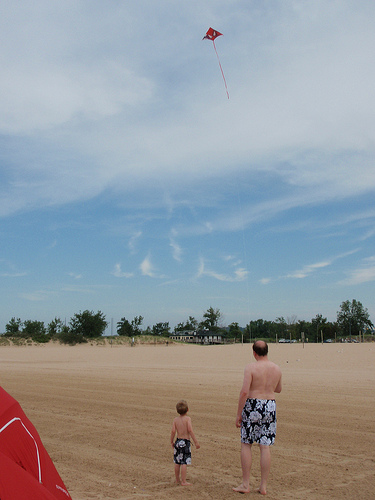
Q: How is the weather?
A: It is clear.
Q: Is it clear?
A: Yes, it is clear.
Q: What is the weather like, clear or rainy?
A: It is clear.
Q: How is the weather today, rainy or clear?
A: It is clear.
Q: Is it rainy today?
A: No, it is clear.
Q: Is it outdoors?
A: Yes, it is outdoors.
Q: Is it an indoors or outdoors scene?
A: It is outdoors.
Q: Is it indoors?
A: No, it is outdoors.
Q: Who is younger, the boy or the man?
A: The boy is younger than the man.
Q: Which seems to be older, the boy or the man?
A: The man is older than the boy.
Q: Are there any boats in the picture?
A: No, there are no boats.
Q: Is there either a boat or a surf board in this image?
A: No, there are no boats or surfboards.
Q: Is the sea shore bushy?
A: Yes, the sea shore is bushy.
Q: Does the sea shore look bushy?
A: Yes, the sea shore is bushy.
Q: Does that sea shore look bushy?
A: Yes, the sea shore is bushy.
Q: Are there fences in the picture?
A: No, there are no fences.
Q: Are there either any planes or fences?
A: No, there are no fences or planes.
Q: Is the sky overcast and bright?
A: No, the sky is bright but clear.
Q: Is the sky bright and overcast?
A: No, the sky is bright but clear.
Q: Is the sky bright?
A: Yes, the sky is bright.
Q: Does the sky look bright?
A: Yes, the sky is bright.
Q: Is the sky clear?
A: Yes, the sky is clear.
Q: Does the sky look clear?
A: Yes, the sky is clear.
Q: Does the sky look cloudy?
A: No, the sky is clear.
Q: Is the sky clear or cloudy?
A: The sky is clear.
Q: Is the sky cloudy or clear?
A: The sky is clear.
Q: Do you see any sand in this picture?
A: Yes, there is sand.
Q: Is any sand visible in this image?
A: Yes, there is sand.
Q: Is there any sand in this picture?
A: Yes, there is sand.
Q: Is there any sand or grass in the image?
A: Yes, there is sand.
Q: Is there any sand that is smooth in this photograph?
A: Yes, there is smooth sand.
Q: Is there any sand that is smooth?
A: Yes, there is sand that is smooth.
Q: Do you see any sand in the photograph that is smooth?
A: Yes, there is sand that is smooth.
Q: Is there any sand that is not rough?
A: Yes, there is smooth sand.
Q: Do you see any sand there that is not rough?
A: Yes, there is smooth sand.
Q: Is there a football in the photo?
A: No, there are no footballs.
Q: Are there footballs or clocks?
A: No, there are no footballs or clocks.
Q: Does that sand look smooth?
A: Yes, the sand is smooth.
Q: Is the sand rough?
A: No, the sand is smooth.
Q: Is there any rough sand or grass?
A: No, there is sand but it is smooth.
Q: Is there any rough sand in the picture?
A: No, there is sand but it is smooth.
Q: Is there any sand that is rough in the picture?
A: No, there is sand but it is smooth.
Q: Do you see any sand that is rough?
A: No, there is sand but it is smooth.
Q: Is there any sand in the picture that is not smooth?
A: No, there is sand but it is smooth.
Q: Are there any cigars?
A: No, there are no cigars.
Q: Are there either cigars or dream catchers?
A: No, there are no cigars or dream catchers.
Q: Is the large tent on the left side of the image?
A: Yes, the tent is on the left of the image.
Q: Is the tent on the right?
A: No, the tent is on the left of the image.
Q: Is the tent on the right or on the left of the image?
A: The tent is on the left of the image.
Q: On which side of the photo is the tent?
A: The tent is on the left of the image.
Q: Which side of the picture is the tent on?
A: The tent is on the left of the image.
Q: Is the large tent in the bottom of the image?
A: Yes, the tent is in the bottom of the image.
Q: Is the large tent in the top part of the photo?
A: No, the tent is in the bottom of the image.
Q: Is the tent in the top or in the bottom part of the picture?
A: The tent is in the bottom of the image.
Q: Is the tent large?
A: Yes, the tent is large.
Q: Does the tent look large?
A: Yes, the tent is large.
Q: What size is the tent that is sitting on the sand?
A: The tent is large.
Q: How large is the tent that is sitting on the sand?
A: The tent is large.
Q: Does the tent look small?
A: No, the tent is large.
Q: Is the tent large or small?
A: The tent is large.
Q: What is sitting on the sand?
A: The tent is sitting on the sand.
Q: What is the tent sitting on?
A: The tent is sitting on the sand.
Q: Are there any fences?
A: No, there are no fences.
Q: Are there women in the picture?
A: No, there are no women.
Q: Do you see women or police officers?
A: No, there are no women or police officers.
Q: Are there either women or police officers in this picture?
A: No, there are no women or police officers.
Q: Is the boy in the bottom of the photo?
A: Yes, the boy is in the bottom of the image.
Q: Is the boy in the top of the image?
A: No, the boy is in the bottom of the image.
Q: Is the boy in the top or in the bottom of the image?
A: The boy is in the bottom of the image.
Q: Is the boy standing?
A: Yes, the boy is standing.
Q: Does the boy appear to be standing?
A: Yes, the boy is standing.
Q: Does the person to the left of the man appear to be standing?
A: Yes, the boy is standing.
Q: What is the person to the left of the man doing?
A: The boy is standing.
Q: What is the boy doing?
A: The boy is standing.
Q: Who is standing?
A: The boy is standing.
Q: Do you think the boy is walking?
A: No, the boy is standing.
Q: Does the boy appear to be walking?
A: No, the boy is standing.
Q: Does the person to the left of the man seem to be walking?
A: No, the boy is standing.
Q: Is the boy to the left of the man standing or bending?
A: The boy is standing.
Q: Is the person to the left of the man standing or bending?
A: The boy is standing.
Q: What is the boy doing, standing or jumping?
A: The boy is standing.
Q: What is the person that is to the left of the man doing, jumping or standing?
A: The boy is standing.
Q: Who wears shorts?
A: The boy wears shorts.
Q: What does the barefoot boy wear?
A: The boy wears shorts.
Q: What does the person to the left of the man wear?
A: The boy wears shorts.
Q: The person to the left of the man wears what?
A: The boy wears shorts.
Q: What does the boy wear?
A: The boy wears shorts.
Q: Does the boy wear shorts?
A: Yes, the boy wears shorts.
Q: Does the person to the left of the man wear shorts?
A: Yes, the boy wears shorts.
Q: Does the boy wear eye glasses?
A: No, the boy wears shorts.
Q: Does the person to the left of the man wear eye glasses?
A: No, the boy wears shorts.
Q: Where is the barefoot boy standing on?
A: The boy is standing on the sand.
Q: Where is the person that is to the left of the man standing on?
A: The boy is standing on the sand.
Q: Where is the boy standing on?
A: The boy is standing on the sand.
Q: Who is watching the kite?
A: The boy is watching the kite.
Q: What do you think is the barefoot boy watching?
A: The boy is watching the kite.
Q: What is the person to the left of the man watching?
A: The boy is watching the kite.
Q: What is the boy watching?
A: The boy is watching the kite.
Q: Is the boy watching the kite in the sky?
A: Yes, the boy is watching the kite.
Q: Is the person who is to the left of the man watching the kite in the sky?
A: Yes, the boy is watching the kite.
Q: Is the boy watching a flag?
A: No, the boy is watching the kite.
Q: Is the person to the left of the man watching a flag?
A: No, the boy is watching the kite.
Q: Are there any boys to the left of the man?
A: Yes, there is a boy to the left of the man.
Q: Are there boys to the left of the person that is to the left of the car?
A: Yes, there is a boy to the left of the man.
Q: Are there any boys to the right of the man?
A: No, the boy is to the left of the man.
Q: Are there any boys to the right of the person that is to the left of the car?
A: No, the boy is to the left of the man.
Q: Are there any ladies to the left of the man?
A: No, there is a boy to the left of the man.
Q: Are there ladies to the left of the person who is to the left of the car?
A: No, there is a boy to the left of the man.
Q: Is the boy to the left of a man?
A: Yes, the boy is to the left of a man.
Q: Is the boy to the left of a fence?
A: No, the boy is to the left of a man.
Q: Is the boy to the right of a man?
A: No, the boy is to the left of a man.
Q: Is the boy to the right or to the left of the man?
A: The boy is to the left of the man.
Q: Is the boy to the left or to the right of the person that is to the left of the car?
A: The boy is to the left of the man.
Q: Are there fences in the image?
A: No, there are no fences.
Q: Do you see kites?
A: Yes, there is a kite.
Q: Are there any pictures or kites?
A: Yes, there is a kite.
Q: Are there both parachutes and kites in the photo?
A: No, there is a kite but no parachutes.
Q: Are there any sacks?
A: No, there are no sacks.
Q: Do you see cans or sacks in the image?
A: No, there are no sacks or cans.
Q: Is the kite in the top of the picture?
A: Yes, the kite is in the top of the image.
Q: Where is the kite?
A: The kite is in the sky.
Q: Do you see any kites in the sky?
A: Yes, there is a kite in the sky.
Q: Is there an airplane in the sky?
A: No, there is a kite in the sky.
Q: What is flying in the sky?
A: The kite is flying in the sky.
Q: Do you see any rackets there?
A: No, there are no rackets.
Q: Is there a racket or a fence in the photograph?
A: No, there are no rackets or fences.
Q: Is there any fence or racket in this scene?
A: No, there are no rackets or fences.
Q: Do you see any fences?
A: No, there are no fences.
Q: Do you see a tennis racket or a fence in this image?
A: No, there are no fences or rackets.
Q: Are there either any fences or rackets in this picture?
A: No, there are no fences or rackets.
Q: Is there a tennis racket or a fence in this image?
A: No, there are no fences or rackets.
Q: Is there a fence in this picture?
A: No, there are no fences.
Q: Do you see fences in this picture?
A: No, there are no fences.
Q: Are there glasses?
A: No, there are no glasses.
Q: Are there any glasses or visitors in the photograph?
A: No, there are no glasses or visitors.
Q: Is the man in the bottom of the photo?
A: Yes, the man is in the bottom of the image.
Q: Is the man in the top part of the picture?
A: No, the man is in the bottom of the image.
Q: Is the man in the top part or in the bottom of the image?
A: The man is in the bottom of the image.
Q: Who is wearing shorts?
A: The man is wearing shorts.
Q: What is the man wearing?
A: The man is wearing shorts.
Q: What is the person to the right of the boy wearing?
A: The man is wearing shorts.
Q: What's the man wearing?
A: The man is wearing shorts.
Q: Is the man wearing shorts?
A: Yes, the man is wearing shorts.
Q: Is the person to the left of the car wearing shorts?
A: Yes, the man is wearing shorts.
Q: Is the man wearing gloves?
A: No, the man is wearing shorts.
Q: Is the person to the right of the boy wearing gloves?
A: No, the man is wearing shorts.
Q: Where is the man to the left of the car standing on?
A: The man is standing on the sand.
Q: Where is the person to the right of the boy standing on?
A: The man is standing on the sand.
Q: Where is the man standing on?
A: The man is standing on the sand.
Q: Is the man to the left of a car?
A: Yes, the man is to the left of a car.